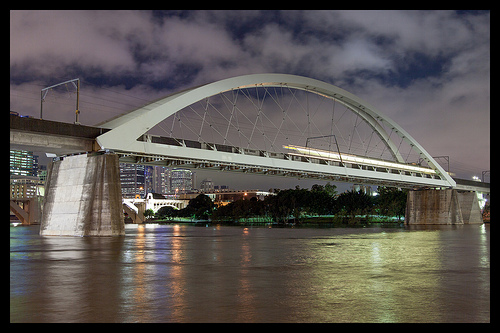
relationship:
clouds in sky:
[322, 25, 457, 112] [18, 13, 475, 158]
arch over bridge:
[119, 68, 458, 160] [38, 73, 484, 237]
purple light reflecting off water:
[152, 224, 170, 321] [140, 225, 448, 312]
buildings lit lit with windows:
[22, 152, 209, 194] [7, 150, 37, 172]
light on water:
[319, 234, 419, 320] [140, 225, 448, 312]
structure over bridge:
[37, 76, 86, 119] [120, 64, 464, 187]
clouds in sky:
[70, 29, 148, 88] [147, 56, 197, 93]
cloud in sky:
[146, 14, 251, 74] [1, 9, 496, 195]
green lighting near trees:
[157, 212, 406, 225] [157, 188, 408, 212]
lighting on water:
[132, 221, 153, 253] [140, 225, 448, 312]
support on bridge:
[36, 150, 129, 238] [38, 73, 484, 237]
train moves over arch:
[282, 144, 455, 179] [94, 72, 456, 186]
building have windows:
[119, 157, 154, 199] [122, 167, 134, 186]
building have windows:
[119, 157, 154, 199] [171, 171, 189, 187]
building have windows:
[5, 149, 39, 210] [10, 150, 32, 170]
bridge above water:
[16, 50, 498, 233] [140, 225, 448, 312]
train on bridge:
[282, 144, 456, 179] [28, 105, 497, 260]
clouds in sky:
[322, 25, 457, 112] [10, 11, 493, 174]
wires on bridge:
[227, 100, 337, 155] [23, 88, 491, 232]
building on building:
[5, 149, 39, 210] [10, 147, 39, 174]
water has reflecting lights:
[140, 225, 448, 312] [135, 224, 143, 271]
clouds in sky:
[6, 16, 136, 78] [1, 9, 496, 195]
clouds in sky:
[322, 25, 457, 112] [1, 9, 496, 195]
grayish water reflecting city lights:
[10, 223, 489, 319] [11, 155, 180, 209]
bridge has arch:
[38, 73, 484, 237] [146, 77, 384, 175]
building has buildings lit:
[5, 152, 42, 199] [11, 152, 22, 169]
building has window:
[5, 152, 42, 199] [19, 164, 26, 168]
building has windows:
[119, 157, 154, 194] [124, 165, 139, 183]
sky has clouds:
[9, 10, 497, 65] [322, 25, 457, 112]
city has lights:
[11, 147, 271, 224] [463, 172, 489, 215]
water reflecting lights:
[140, 225, 448, 312] [463, 172, 489, 215]